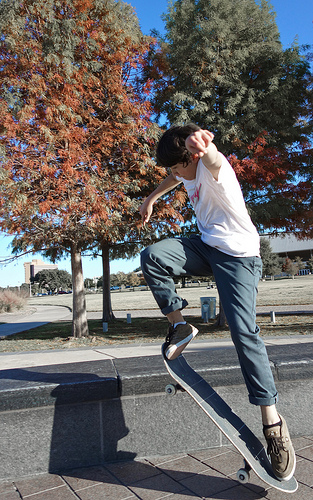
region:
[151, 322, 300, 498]
A black skateboard with white wheels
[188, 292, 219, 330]
A gray electrical box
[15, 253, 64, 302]
Tall tan building in distance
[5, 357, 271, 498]
Shadow cast by boy and skateboard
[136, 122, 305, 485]
Boy doing trick on skateboard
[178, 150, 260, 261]
A white shirt with red lettering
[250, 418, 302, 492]
Brown shoe with shoe laces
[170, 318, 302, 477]
One sock is white one sock is black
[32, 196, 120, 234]
Red leaves on a tree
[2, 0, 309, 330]
Two large trees behind boy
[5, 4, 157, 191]
green and brown leaves on a tree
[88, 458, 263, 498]
the shadow from a skateboard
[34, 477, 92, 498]
concrete tiles on the ground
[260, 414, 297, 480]
a brown canvas shoe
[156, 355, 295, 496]
a black skateboard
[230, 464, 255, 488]
a white wheel on a skateboard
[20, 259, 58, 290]
a tall building in the distance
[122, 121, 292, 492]
a boy doing a trick on a skateboard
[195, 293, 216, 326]
a metal post in the background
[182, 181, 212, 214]
red writing on a white shirt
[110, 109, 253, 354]
this is a boy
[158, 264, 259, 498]
the boy is skating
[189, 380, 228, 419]
this is a skate board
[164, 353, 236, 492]
the board is raised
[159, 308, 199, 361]
the feet is bent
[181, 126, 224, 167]
the hand is apart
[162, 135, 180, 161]
the hair is short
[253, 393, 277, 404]
the trouser is folded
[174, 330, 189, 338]
the shoe is brown in color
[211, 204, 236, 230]
the t shirt is white in color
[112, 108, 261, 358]
kid riding a skateboard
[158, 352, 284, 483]
board beneath the kid's feet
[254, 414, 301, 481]
shoe on the boy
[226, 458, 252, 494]
wheel on the board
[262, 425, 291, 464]
laces on the shoe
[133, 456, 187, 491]
ground beneath the board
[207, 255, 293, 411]
pant leg of the boy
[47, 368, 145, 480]
shadow on the ground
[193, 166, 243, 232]
white shirt on kid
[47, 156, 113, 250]
tree behind the kid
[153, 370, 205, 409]
these are the wheels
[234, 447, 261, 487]
these are the back wheels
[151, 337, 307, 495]
this is a skateboard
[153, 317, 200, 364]
this is the right shoe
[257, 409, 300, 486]
this is the left shoe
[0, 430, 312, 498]
this is the ground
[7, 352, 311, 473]
this is a wall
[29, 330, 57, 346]
this is the grass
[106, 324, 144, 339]
these are the leaves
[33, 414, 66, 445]
this is the concrete